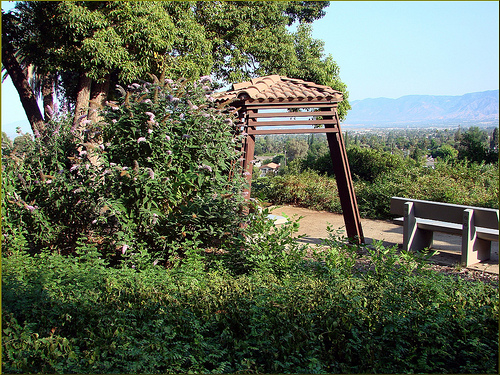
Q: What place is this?
A: It is a garden.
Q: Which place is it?
A: It is a garden.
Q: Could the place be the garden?
A: Yes, it is the garden.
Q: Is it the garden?
A: Yes, it is the garden.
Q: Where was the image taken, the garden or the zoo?
A: It was taken at the garden.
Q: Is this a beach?
A: No, it is a garden.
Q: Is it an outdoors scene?
A: Yes, it is outdoors.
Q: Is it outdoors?
A: Yes, it is outdoors.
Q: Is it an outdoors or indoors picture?
A: It is outdoors.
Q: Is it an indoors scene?
A: No, it is outdoors.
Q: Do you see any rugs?
A: No, there are no rugs.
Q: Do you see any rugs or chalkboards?
A: No, there are no rugs or chalkboards.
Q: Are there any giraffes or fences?
A: No, there are no fences or giraffes.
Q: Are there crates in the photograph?
A: No, there are no crates.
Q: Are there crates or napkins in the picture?
A: No, there are no crates or napkins.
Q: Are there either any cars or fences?
A: No, there are no fences or cars.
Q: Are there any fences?
A: No, there are no fences.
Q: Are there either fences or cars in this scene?
A: No, there are no fences or cars.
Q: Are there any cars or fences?
A: No, there are no fences or cars.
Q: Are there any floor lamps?
A: No, there are no floor lamps.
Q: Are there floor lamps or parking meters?
A: No, there are no floor lamps or parking meters.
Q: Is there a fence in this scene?
A: No, there are no fences.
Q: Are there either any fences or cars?
A: No, there are no fences or cars.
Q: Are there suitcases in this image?
A: No, there are no suitcases.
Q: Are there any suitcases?
A: No, there are no suitcases.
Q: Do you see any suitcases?
A: No, there are no suitcases.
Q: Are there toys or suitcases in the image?
A: No, there are no suitcases or toys.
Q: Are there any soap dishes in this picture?
A: No, there are no soap dishes.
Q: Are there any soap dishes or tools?
A: No, there are no soap dishes or tools.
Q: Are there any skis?
A: No, there are no skis.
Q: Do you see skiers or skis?
A: No, there are no skis or skiers.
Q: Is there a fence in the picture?
A: No, there are no fences.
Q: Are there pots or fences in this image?
A: No, there are no fences or pots.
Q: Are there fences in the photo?
A: No, there are no fences.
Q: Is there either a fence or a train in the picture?
A: No, there are no fences or trains.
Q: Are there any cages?
A: No, there are no cages.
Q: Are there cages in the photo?
A: No, there are no cages.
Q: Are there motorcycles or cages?
A: No, there are no cages or motorcycles.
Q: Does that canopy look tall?
A: Yes, the canopy is tall.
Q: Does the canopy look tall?
A: Yes, the canopy is tall.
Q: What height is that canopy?
A: The canopy is tall.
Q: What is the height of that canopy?
A: The canopy is tall.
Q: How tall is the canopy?
A: The canopy is tall.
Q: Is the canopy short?
A: No, the canopy is tall.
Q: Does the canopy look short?
A: No, the canopy is tall.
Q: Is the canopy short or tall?
A: The canopy is tall.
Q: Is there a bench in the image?
A: Yes, there is a bench.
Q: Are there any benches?
A: Yes, there is a bench.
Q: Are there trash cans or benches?
A: Yes, there is a bench.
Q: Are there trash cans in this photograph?
A: No, there are no trash cans.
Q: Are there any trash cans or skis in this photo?
A: No, there are no trash cans or skis.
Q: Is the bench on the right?
A: Yes, the bench is on the right of the image.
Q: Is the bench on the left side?
A: No, the bench is on the right of the image.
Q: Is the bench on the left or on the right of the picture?
A: The bench is on the right of the image.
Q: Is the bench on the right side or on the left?
A: The bench is on the right of the image.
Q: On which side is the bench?
A: The bench is on the right of the image.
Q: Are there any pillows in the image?
A: No, there are no pillows.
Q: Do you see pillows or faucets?
A: No, there are no pillows or faucets.